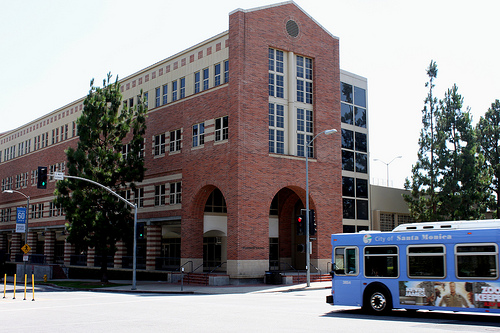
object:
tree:
[399, 60, 493, 222]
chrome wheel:
[364, 287, 392, 317]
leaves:
[50, 70, 147, 251]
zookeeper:
[438, 280, 471, 309]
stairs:
[183, 270, 207, 286]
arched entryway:
[191, 182, 228, 275]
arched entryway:
[268, 184, 318, 275]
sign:
[15, 207, 26, 233]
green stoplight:
[37, 166, 49, 190]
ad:
[398, 280, 498, 311]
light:
[298, 217, 302, 222]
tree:
[474, 99, 498, 220]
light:
[324, 128, 338, 135]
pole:
[303, 131, 323, 288]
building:
[0, 0, 418, 288]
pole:
[32, 273, 36, 302]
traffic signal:
[36, 165, 47, 189]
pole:
[64, 175, 138, 291]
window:
[295, 52, 314, 104]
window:
[296, 106, 314, 159]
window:
[269, 102, 286, 155]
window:
[266, 45, 284, 99]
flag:
[15, 205, 26, 233]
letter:
[421, 234, 451, 241]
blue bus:
[325, 219, 500, 315]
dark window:
[454, 242, 499, 280]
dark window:
[406, 244, 446, 280]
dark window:
[362, 245, 399, 279]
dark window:
[343, 245, 358, 275]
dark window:
[334, 247, 346, 274]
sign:
[21, 244, 30, 253]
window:
[354, 86, 366, 109]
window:
[353, 106, 367, 129]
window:
[355, 132, 367, 152]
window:
[341, 149, 354, 172]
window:
[356, 200, 369, 220]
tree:
[48, 69, 150, 287]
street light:
[304, 128, 341, 287]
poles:
[2, 272, 28, 300]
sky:
[0, 3, 497, 184]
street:
[2, 283, 500, 333]